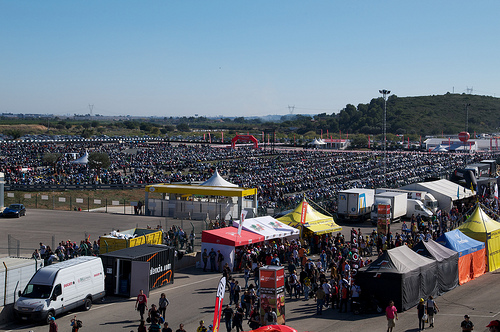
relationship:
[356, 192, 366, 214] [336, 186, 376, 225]
design on truck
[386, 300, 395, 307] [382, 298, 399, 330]
head on person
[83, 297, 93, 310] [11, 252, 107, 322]
tire on van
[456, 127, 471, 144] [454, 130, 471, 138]
balloon with stripe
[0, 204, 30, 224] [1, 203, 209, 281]
car on parking lot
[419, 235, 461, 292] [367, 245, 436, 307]
black tent side by side black tent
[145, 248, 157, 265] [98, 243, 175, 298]
stripe on trailer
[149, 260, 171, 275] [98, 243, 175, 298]
letters on trailer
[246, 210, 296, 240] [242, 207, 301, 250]
logos on white tent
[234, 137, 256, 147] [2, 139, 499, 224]
arche in front of lot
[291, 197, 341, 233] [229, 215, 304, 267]
tent top in front of tent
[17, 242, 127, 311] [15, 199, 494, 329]
van on road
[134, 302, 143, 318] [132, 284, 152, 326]
leg on person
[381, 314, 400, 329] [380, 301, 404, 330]
leg on person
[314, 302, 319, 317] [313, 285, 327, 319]
leg on person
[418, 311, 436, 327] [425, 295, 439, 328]
leg on people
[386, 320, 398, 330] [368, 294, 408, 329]
leg on person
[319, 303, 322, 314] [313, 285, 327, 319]
leg on person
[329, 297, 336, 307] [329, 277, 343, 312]
leg on person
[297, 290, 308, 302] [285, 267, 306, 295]
leg on person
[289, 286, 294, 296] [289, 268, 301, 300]
leg of a person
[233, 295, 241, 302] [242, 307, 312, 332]
leg of a person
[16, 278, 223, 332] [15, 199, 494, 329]
part of a road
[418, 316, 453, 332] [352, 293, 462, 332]
people are walking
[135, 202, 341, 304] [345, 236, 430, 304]
part of a tent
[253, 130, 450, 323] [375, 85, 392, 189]
part of light pole